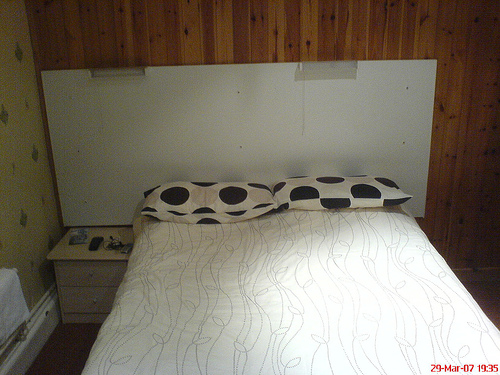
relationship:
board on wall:
[38, 62, 443, 224] [28, 4, 500, 274]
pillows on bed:
[123, 173, 430, 226] [92, 199, 499, 375]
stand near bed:
[40, 226, 138, 325] [92, 199, 499, 375]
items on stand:
[70, 226, 132, 255] [40, 226, 138, 325]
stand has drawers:
[40, 226, 138, 325] [52, 261, 126, 321]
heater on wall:
[3, 262, 56, 362] [28, 4, 500, 274]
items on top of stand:
[70, 226, 132, 255] [40, 226, 138, 325]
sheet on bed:
[123, 224, 483, 368] [92, 199, 499, 375]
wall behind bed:
[28, 4, 500, 274] [92, 199, 499, 375]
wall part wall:
[28, 4, 500, 274] [28, 0, 500, 270]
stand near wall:
[40, 226, 138, 325] [28, 4, 500, 274]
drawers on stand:
[52, 261, 126, 321] [40, 226, 138, 325]